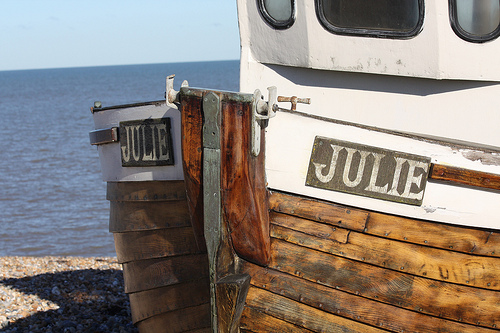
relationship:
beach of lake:
[3, 254, 126, 331] [0, 100, 222, 329]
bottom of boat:
[119, 177, 499, 324] [121, 188, 406, 330]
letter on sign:
[368, 151, 423, 217] [272, 130, 484, 223]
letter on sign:
[313, 139, 335, 184] [300, 130, 429, 207]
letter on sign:
[154, 123, 170, 162] [118, 117, 173, 165]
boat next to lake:
[87, 79, 482, 310] [10, 57, 248, 260]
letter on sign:
[388, 154, 405, 198] [307, 133, 433, 220]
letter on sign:
[118, 124, 132, 164] [118, 116, 177, 168]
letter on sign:
[130, 124, 141, 162] [118, 116, 177, 168]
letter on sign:
[138, 125, 154, 160] [118, 116, 177, 168]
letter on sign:
[147, 124, 159, 160] [118, 116, 177, 168]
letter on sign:
[154, 123, 170, 162] [118, 116, 177, 168]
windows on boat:
[322, 3, 430, 38] [81, 0, 498, 332]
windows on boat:
[449, 1, 499, 37] [81, 0, 498, 332]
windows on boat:
[257, 2, 309, 37] [81, 0, 498, 332]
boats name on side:
[110, 117, 180, 172] [251, 59, 471, 299]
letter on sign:
[404, 156, 429, 201] [307, 134, 434, 209]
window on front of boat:
[311, 0, 424, 38] [97, 12, 487, 331]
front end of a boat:
[163, 1, 498, 330] [97, 12, 487, 331]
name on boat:
[298, 128, 421, 197] [97, 12, 487, 331]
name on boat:
[108, 112, 190, 174] [97, 12, 487, 331]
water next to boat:
[11, 115, 81, 221] [81, 0, 498, 332]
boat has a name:
[158, 26, 495, 311] [300, 133, 433, 209]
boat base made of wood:
[199, 165, 466, 332] [213, 186, 498, 331]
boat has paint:
[97, 12, 487, 331] [437, 142, 498, 173]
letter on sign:
[118, 125, 133, 165] [301, 130, 433, 213]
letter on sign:
[126, 120, 143, 164] [115, 120, 184, 175]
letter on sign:
[135, 122, 155, 164] [115, 120, 184, 175]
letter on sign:
[153, 122, 174, 164] [115, 120, 184, 175]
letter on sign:
[361, 144, 386, 198] [115, 120, 184, 175]